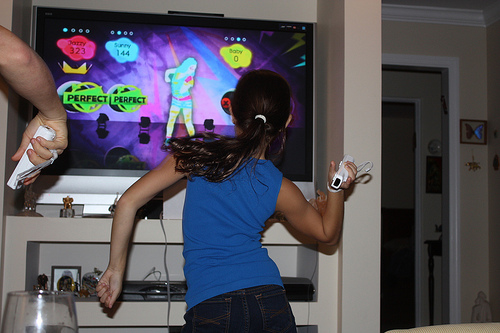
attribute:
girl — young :
[202, 108, 277, 296]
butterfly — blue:
[468, 122, 483, 137]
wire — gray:
[127, 210, 188, 330]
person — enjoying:
[99, 65, 372, 325]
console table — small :
[422, 220, 444, 326]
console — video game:
[277, 268, 330, 314]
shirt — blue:
[181, 150, 281, 306]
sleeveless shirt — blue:
[180, 155, 285, 310]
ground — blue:
[315, 167, 345, 187]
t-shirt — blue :
[181, 147, 284, 316]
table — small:
[420, 235, 448, 326]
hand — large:
[8, 112, 65, 182]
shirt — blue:
[180, 154, 280, 287]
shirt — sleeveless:
[185, 156, 284, 299]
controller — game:
[334, 160, 352, 190]